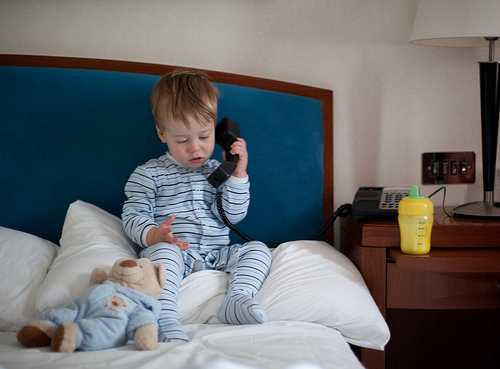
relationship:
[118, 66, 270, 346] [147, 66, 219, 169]
boy has head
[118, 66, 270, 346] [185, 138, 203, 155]
boy has nose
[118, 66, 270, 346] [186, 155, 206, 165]
boy has mouth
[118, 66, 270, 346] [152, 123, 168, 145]
boy has ear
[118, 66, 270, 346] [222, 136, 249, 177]
boy has hand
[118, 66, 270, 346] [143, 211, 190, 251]
boy has hand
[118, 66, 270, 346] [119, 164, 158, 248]
boy has arm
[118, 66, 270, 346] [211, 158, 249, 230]
boy has arm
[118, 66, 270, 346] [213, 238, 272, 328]
boy has leg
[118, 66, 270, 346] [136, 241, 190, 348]
boy has leg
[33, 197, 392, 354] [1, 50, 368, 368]
pillow on top of bed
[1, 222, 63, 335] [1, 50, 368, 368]
pillow on top of bed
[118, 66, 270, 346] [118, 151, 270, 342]
boy wearing outfit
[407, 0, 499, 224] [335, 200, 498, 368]
lamp set on table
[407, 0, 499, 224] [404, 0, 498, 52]
lamp has shade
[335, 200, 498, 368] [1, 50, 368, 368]
table next to bed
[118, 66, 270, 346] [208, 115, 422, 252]
boy holding telephone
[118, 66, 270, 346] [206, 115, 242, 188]
boy holding receiver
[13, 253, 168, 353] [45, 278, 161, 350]
teddy bear wearing pajamas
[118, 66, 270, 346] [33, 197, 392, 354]
boy sitting on top of pillow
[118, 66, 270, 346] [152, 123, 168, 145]
boy has right ear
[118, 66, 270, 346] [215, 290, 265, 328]
boy has left foot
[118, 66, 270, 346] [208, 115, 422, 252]
boy holding onto telephone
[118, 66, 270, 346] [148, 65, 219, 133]
boy has hair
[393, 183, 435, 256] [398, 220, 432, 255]
cup contains milk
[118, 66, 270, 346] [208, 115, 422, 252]
boy talking on telephone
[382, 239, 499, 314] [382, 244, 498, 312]
drawer made of wood